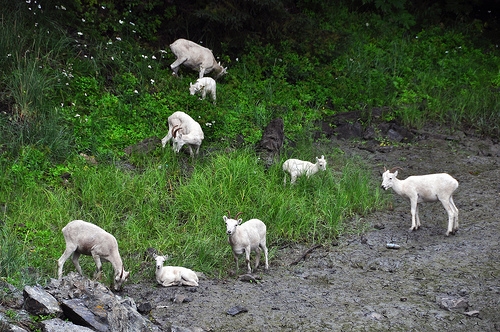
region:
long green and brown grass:
[42, 121, 83, 163]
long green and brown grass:
[128, 175, 162, 195]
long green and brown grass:
[204, 146, 245, 190]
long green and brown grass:
[28, 91, 98, 138]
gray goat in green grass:
[34, 215, 125, 279]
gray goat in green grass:
[141, 249, 216, 293]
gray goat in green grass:
[205, 205, 277, 277]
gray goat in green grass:
[258, 135, 322, 187]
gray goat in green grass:
[377, 162, 462, 263]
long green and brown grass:
[120, 178, 158, 203]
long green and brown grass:
[147, 173, 182, 214]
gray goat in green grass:
[39, 218, 126, 277]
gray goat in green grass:
[192, 197, 281, 273]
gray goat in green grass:
[252, 135, 339, 201]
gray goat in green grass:
[149, 101, 215, 162]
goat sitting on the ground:
[136, 241, 223, 313]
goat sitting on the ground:
[135, 246, 219, 296]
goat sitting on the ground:
[145, 248, 200, 292]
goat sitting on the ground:
[138, 232, 221, 298]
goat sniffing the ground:
[31, 199, 138, 294]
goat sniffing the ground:
[30, 204, 145, 300]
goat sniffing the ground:
[40, 209, 139, 292]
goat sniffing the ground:
[34, 199, 151, 311]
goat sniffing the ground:
[34, 201, 169, 330]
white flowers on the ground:
[21, 6, 156, 101]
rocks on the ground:
[17, 273, 134, 322]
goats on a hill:
[19, 35, 484, 282]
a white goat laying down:
[152, 246, 198, 287]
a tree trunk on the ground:
[252, 110, 284, 165]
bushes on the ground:
[249, 45, 484, 93]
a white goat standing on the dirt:
[373, 160, 475, 236]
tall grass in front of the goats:
[19, 155, 254, 215]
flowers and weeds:
[17, 13, 124, 82]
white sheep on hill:
[55, 21, 447, 295]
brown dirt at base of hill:
[265, 254, 390, 329]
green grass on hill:
[37, 101, 339, 255]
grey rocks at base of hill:
[35, 274, 147, 328]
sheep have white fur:
[384, 155, 454, 236]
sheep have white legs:
[394, 198, 459, 233]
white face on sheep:
[370, 164, 397, 195]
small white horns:
[370, 163, 404, 184]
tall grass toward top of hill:
[15, 24, 180, 126]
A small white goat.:
[378, 165, 461, 234]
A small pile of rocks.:
[0, 270, 158, 330]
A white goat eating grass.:
[164, 35, 227, 79]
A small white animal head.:
[381, 163, 402, 189]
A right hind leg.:
[55, 238, 76, 278]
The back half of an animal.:
[179, 265, 200, 285]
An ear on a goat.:
[391, 165, 401, 174]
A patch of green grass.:
[0, 140, 382, 285]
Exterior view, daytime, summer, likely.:
[5, 0, 495, 328]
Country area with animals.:
[2, 3, 497, 330]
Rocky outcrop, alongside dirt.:
[2, 274, 148, 330]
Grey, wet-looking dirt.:
[275, 261, 475, 330]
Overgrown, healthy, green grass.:
[20, 154, 255, 214]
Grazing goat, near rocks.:
[41, 216, 134, 293]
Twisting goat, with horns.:
[154, 101, 206, 164]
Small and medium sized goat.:
[278, 156, 472, 233]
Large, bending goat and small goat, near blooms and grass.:
[40, 17, 246, 104]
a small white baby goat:
[266, 151, 327, 188]